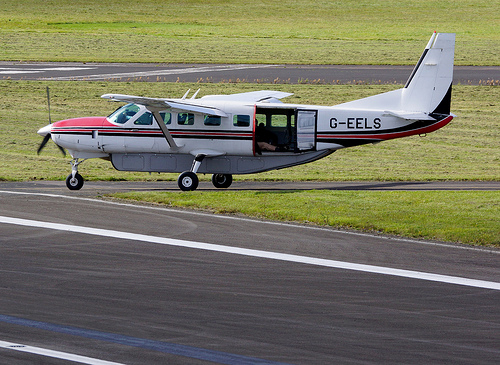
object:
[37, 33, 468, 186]
plane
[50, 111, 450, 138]
stripes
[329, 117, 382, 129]
letters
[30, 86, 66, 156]
propeller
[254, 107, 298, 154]
door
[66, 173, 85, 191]
wheels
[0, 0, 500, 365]
field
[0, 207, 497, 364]
tarmac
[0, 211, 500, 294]
lines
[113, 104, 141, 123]
cockpit window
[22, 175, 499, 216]
ground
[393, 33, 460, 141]
tail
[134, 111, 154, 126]
windows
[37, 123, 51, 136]
rotor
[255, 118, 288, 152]
passengers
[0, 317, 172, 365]
line